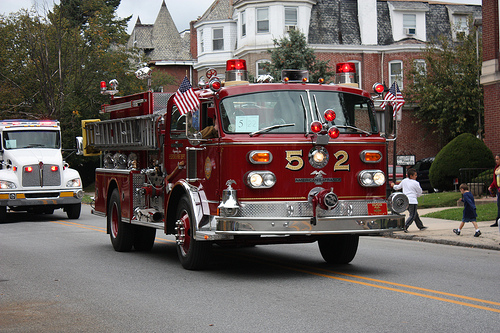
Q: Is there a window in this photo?
A: Yes, there is a window.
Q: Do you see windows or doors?
A: Yes, there is a window.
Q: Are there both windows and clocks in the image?
A: No, there is a window but no clocks.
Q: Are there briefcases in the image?
A: No, there are no briefcases.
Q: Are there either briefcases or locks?
A: No, there are no briefcases or locks.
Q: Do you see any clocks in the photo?
A: No, there are no clocks.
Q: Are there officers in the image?
A: No, there are no officers.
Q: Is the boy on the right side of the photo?
A: Yes, the boy is on the right of the image.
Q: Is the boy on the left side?
A: No, the boy is on the right of the image.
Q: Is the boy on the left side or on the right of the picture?
A: The boy is on the right of the image.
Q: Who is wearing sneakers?
A: The boy is wearing sneakers.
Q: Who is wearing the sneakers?
A: The boy is wearing sneakers.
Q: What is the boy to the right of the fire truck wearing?
A: The boy is wearing sneakers.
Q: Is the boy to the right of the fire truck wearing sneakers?
A: Yes, the boy is wearing sneakers.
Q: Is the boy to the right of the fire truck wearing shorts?
A: No, the boy is wearing sneakers.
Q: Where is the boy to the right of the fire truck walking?
A: The boy is walking on the sidewalk.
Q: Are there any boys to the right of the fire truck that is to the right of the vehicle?
A: Yes, there is a boy to the right of the fire truck.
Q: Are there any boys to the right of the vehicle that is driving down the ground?
A: Yes, there is a boy to the right of the fire truck.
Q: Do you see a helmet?
A: No, there are no helmets.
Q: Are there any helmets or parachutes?
A: No, there are no helmets or parachutes.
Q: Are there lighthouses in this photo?
A: No, there are no lighthouses.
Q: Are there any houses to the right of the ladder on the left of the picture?
A: Yes, there is a house to the right of the ladder.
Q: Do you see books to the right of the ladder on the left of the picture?
A: No, there is a house to the right of the ladder.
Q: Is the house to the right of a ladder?
A: Yes, the house is to the right of a ladder.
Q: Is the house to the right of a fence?
A: No, the house is to the right of a ladder.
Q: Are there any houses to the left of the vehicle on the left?
A: No, the house is to the right of the vehicle.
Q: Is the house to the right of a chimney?
A: No, the house is to the right of the vehicle.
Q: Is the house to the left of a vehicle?
A: No, the house is to the right of a vehicle.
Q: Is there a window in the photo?
A: Yes, there is a window.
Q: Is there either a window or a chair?
A: Yes, there is a window.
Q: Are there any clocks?
A: No, there are no clocks.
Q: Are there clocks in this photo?
A: No, there are no clocks.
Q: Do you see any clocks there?
A: No, there are no clocks.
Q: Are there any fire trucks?
A: Yes, there is a fire truck.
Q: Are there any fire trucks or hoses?
A: Yes, there is a fire truck.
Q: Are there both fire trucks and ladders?
A: Yes, there are both a fire truck and a ladder.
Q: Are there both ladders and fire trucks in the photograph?
A: Yes, there are both a fire truck and a ladder.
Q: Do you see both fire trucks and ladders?
A: Yes, there are both a fire truck and a ladder.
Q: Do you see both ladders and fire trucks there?
A: Yes, there are both a fire truck and a ladder.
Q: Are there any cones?
A: No, there are no cones.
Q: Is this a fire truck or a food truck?
A: This is a fire truck.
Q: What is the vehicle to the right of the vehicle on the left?
A: The vehicle is a fire truck.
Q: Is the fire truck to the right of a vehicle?
A: Yes, the fire truck is to the right of a vehicle.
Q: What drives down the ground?
A: The fire truck drives down the ground.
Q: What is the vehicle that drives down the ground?
A: The vehicle is a fire truck.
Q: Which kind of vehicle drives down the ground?
A: The vehicle is a fire truck.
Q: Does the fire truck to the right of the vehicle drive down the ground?
A: Yes, the fire truck drives down the ground.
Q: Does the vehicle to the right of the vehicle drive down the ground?
A: Yes, the fire truck drives down the ground.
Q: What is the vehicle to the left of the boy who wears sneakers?
A: The vehicle is a fire truck.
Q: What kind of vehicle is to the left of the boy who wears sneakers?
A: The vehicle is a fire truck.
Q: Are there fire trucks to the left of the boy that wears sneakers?
A: Yes, there is a fire truck to the left of the boy.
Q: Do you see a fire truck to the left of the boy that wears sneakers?
A: Yes, there is a fire truck to the left of the boy.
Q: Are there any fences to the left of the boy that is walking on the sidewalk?
A: No, there is a fire truck to the left of the boy.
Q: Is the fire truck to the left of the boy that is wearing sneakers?
A: Yes, the fire truck is to the left of the boy.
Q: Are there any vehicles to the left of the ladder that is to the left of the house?
A: Yes, there is a vehicle to the left of the ladder.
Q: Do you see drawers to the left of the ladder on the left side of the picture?
A: No, there is a vehicle to the left of the ladder.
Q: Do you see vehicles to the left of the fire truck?
A: Yes, there is a vehicle to the left of the fire truck.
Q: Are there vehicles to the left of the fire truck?
A: Yes, there is a vehicle to the left of the fire truck.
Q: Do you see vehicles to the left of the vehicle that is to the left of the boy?
A: Yes, there is a vehicle to the left of the fire truck.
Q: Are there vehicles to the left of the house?
A: Yes, there is a vehicle to the left of the house.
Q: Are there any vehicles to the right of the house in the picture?
A: No, the vehicle is to the left of the house.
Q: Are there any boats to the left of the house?
A: No, there is a vehicle to the left of the house.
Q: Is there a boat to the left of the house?
A: No, there is a vehicle to the left of the house.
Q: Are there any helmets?
A: No, there are no helmets.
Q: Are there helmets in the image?
A: No, there are no helmets.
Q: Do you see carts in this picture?
A: No, there are no carts.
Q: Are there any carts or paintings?
A: No, there are no carts or paintings.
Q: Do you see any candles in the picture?
A: No, there are no candles.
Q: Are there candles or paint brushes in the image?
A: No, there are no candles or paint brushes.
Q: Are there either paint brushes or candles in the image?
A: No, there are no candles or paint brushes.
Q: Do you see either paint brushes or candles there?
A: No, there are no candles or paint brushes.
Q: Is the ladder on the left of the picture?
A: Yes, the ladder is on the left of the image.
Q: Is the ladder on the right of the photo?
A: No, the ladder is on the left of the image.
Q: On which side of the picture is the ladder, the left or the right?
A: The ladder is on the left of the image.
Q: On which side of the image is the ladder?
A: The ladder is on the left of the image.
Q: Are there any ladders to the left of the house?
A: Yes, there is a ladder to the left of the house.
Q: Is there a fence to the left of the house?
A: No, there is a ladder to the left of the house.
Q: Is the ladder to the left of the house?
A: Yes, the ladder is to the left of the house.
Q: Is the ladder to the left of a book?
A: No, the ladder is to the left of the house.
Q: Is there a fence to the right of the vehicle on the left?
A: No, there is a ladder to the right of the vehicle.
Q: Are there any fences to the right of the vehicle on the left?
A: No, there is a ladder to the right of the vehicle.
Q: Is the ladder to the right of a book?
A: No, the ladder is to the right of the vehicle.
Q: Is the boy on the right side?
A: Yes, the boy is on the right of the image.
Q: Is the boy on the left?
A: No, the boy is on the right of the image.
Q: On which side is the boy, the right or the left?
A: The boy is on the right of the image.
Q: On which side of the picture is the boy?
A: The boy is on the right of the image.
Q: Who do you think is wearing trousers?
A: The boy is wearing trousers.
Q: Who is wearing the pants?
A: The boy is wearing trousers.